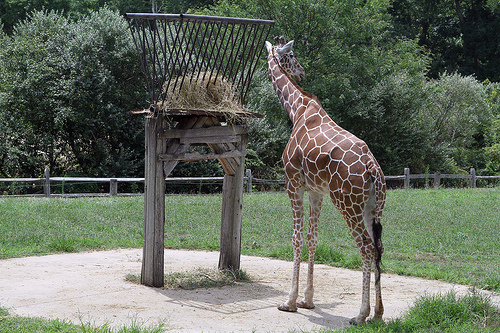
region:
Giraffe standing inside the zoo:
[237, 21, 429, 331]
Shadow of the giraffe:
[305, 300, 352, 330]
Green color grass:
[25, 195, 121, 230]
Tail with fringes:
[365, 185, 406, 292]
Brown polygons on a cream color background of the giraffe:
[292, 121, 352, 191]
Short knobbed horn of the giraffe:
[266, 30, 282, 40]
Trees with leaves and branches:
[26, 18, 148, 150]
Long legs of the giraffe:
[274, 200, 338, 325]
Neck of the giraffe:
[269, 68, 294, 107]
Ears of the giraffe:
[260, 39, 300, 56]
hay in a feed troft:
[157, 58, 252, 134]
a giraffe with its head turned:
[268, 20, 320, 85]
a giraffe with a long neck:
[267, 37, 302, 137]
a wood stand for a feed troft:
[154, 82, 250, 282]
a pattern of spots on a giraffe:
[307, 125, 343, 168]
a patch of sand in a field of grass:
[2, 235, 294, 330]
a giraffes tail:
[368, 174, 389, 281]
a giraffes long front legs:
[285, 191, 318, 312]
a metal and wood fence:
[14, 166, 129, 207]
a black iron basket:
[171, 13, 273, 133]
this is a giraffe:
[242, 15, 413, 317]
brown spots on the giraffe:
[300, 133, 352, 208]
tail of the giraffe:
[360, 140, 407, 287]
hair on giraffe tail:
[360, 199, 393, 289]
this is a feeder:
[126, 7, 277, 154]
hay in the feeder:
[151, 42, 262, 133]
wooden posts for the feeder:
[125, 93, 262, 292]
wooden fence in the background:
[18, 161, 498, 219]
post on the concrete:
[3, 164, 476, 331]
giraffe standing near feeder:
[118, 0, 432, 332]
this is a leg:
[290, 260, 332, 322]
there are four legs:
[249, 217, 401, 314]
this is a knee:
[282, 240, 302, 261]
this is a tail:
[352, 226, 406, 323]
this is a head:
[250, 38, 292, 80]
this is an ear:
[270, 30, 309, 71]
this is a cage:
[142, 43, 202, 120]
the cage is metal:
[164, 49, 259, 194]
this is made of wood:
[95, 191, 185, 313]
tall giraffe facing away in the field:
[259, 31, 398, 331]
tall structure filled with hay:
[113, 1, 269, 306]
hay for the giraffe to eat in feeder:
[107, 8, 352, 163]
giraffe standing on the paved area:
[244, 222, 402, 332]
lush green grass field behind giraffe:
[400, 188, 497, 269]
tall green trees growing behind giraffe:
[20, 5, 125, 167]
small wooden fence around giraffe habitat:
[24, 153, 130, 210]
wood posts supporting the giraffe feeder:
[136, 120, 183, 289]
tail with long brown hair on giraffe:
[360, 157, 393, 295]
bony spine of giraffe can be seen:
[286, 85, 340, 157]